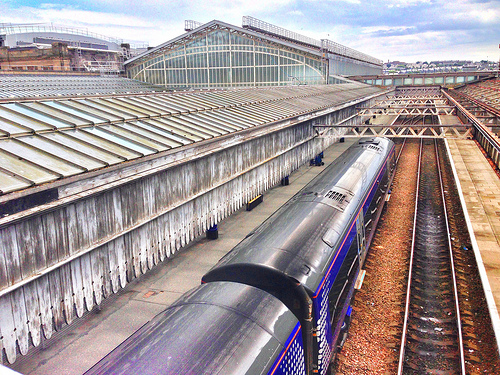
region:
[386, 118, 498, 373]
these are train tracks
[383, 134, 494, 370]
these tracks are empty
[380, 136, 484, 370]
there is no train on these tracks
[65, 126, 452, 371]
this is a passenger train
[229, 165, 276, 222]
this is a bench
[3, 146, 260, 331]
part of a wooden fence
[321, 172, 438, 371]
there are red rocks in between the tracks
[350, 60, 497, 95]
this is an indoor bridge walkway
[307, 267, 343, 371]
there is a white pattern on the side of the train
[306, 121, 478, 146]
Large white metal beam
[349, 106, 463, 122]
Large white metal beam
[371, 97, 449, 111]
Large white metal beam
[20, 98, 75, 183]
Large white metal beam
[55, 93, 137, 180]
Large white metal beam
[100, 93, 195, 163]
Large white metal beam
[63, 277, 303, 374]
the silver blue and red train car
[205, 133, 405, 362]
the silver blue and red train car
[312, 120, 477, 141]
the metal and white support beam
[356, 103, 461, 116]
the metal and white support beam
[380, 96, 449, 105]
the metal and white support beam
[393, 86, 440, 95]
the metal and white support beam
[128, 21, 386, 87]
the large glass building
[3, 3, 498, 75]
the bright blue sky above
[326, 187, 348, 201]
the vent on the top of the train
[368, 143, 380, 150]
the vent on the top of the train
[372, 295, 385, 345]
gravel near side of train tracks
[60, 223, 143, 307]
wooden fence on side of building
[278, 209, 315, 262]
silver top of train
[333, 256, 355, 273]
royal blue area on train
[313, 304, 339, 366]
white designs on side of train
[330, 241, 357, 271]
pink stripe on side of train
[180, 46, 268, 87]
large wall of glass windows on building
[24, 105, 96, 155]
metal roof on top of building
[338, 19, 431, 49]
white clouds in blue sky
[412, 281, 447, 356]
black railroad track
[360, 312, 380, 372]
gravel beside the train tracks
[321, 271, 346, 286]
metalic blue color on train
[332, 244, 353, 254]
pink stripe on top of train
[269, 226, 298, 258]
metallic silver top of train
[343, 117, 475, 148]
metal trellises over trains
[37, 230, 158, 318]
wooden beams on side of building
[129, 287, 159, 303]
orange portion of color on cement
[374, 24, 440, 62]
white clouds in blue sky